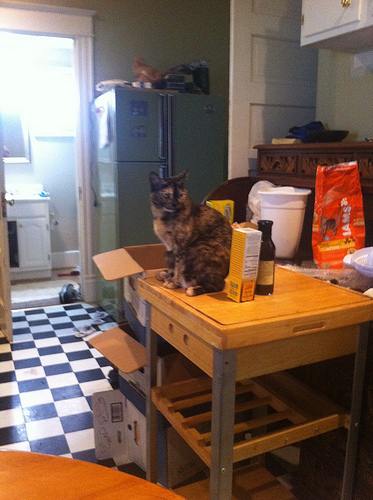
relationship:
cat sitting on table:
[146, 168, 233, 294] [131, 258, 371, 498]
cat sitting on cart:
[146, 168, 233, 294] [127, 264, 371, 499]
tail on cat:
[180, 276, 222, 299] [143, 170, 245, 301]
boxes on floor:
[85, 235, 253, 483] [3, 294, 371, 498]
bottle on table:
[247, 219, 281, 299] [131, 258, 371, 498]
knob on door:
[300, 14, 306, 25] [300, 9, 361, 42]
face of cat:
[149, 187, 189, 213] [146, 168, 233, 294]